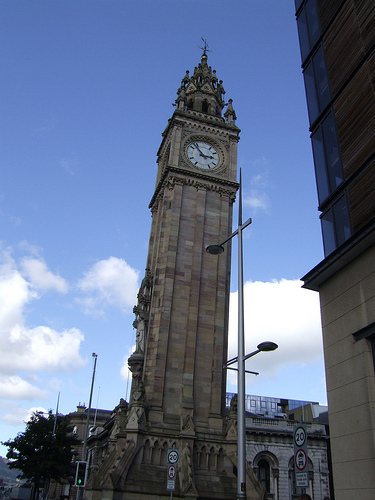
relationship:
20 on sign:
[295, 427, 305, 445] [289, 424, 310, 449]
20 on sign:
[168, 452, 177, 464] [166, 449, 183, 462]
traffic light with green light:
[70, 458, 91, 490] [75, 475, 83, 484]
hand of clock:
[192, 139, 203, 154] [183, 130, 227, 172]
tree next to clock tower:
[6, 406, 92, 498] [111, 32, 242, 497]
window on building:
[253, 449, 279, 498] [43, 36, 375, 498]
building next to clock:
[43, 36, 375, 498] [128, 35, 240, 497]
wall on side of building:
[314, 259, 374, 499] [293, 0, 373, 499]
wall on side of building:
[128, 191, 162, 410] [43, 36, 332, 498]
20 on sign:
[295, 427, 305, 445] [292, 422, 309, 486]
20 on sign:
[168, 452, 177, 464] [165, 448, 178, 491]